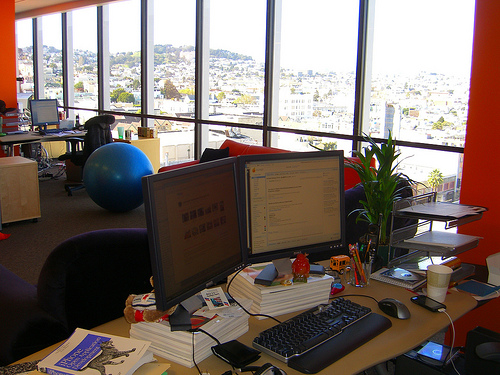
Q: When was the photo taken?
A: Daytime.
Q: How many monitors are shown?
A: Three.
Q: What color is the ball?
A: Blue.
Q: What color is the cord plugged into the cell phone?
A: White.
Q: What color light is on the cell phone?
A: Blue.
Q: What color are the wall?
A: Orange.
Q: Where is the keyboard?
A: Desk.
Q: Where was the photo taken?
A: In the office.